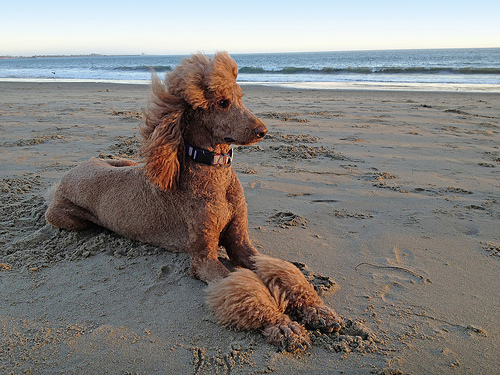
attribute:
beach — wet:
[1, 72, 499, 373]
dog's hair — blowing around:
[148, 67, 184, 108]